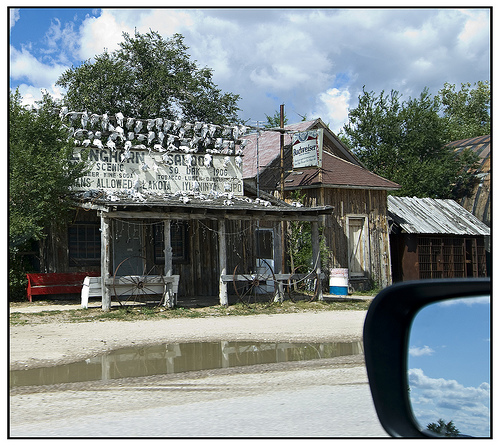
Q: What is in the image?
A: Mirror.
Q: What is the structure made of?
A: Wood.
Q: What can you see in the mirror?
A: The sky.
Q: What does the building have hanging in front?
A: A sign.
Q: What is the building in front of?
A: Trees.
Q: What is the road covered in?
A: Water.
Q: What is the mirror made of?
A: Plastic.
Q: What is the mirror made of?
A: Glass.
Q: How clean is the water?
A: Dirty.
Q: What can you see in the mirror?
A: Clouds and trees.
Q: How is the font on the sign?
A: In all Caps.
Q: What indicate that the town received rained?
A: The puddle of water.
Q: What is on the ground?
A: A puddle of water.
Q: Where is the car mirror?
A: To the right of the picture.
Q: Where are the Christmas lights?
A: On the building.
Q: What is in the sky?
A: Clouds.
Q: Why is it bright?
A: It is sunny.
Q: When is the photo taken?
A: Daytime.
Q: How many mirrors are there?
A: One.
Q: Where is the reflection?
A: In the mirror.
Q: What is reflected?
A: The sky and a tree.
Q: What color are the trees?
A: Green.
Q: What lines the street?
A: Buildings.